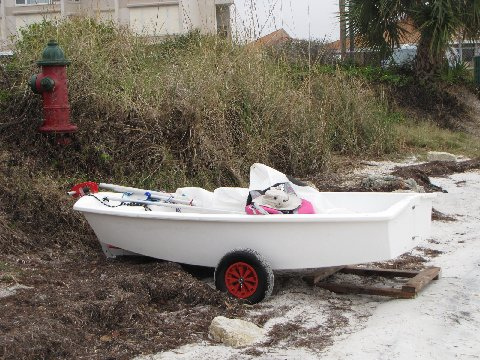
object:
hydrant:
[18, 34, 83, 140]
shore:
[442, 128, 477, 203]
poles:
[101, 196, 204, 211]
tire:
[212, 245, 277, 306]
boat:
[76, 170, 435, 308]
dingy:
[67, 180, 437, 305]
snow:
[414, 320, 448, 346]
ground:
[144, 268, 194, 337]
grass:
[77, 37, 111, 124]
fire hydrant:
[23, 35, 80, 148]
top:
[32, 35, 73, 70]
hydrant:
[28, 30, 78, 134]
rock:
[208, 314, 263, 349]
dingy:
[61, 166, 449, 307]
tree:
[334, 0, 479, 102]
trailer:
[68, 174, 442, 309]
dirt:
[79, 293, 120, 328]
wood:
[392, 253, 443, 302]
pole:
[83, 196, 206, 210]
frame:
[361, 267, 426, 305]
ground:
[448, 269, 477, 305]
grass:
[157, 52, 190, 136]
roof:
[246, 29, 289, 53]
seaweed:
[260, 100, 345, 141]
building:
[4, 4, 239, 58]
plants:
[379, 65, 405, 80]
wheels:
[209, 246, 273, 307]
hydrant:
[27, 41, 81, 137]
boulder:
[203, 308, 276, 349]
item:
[232, 159, 322, 221]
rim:
[227, 266, 257, 294]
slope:
[467, 63, 480, 197]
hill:
[6, 37, 410, 190]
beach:
[2, 182, 54, 358]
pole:
[96, 180, 194, 198]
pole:
[103, 193, 208, 213]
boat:
[64, 159, 434, 306]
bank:
[446, 112, 477, 192]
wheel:
[213, 245, 276, 305]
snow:
[383, 297, 416, 314]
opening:
[26, 75, 37, 95]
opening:
[38, 74, 53, 93]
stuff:
[274, 203, 304, 217]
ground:
[421, 330, 478, 358]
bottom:
[376, 67, 477, 103]